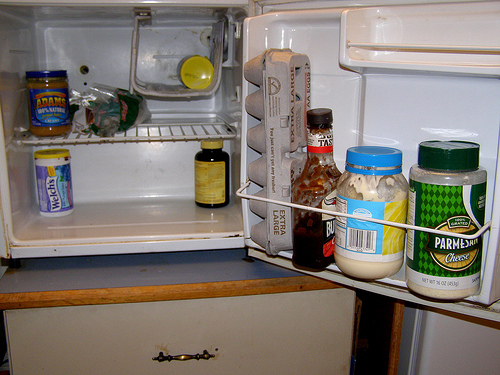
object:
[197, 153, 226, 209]
vitamins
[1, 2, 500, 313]
fridge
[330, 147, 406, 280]
mayonnaise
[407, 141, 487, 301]
parmesan cheese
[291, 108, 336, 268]
barbeque sauce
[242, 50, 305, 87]
eggs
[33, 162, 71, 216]
welch's drink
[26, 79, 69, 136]
sauce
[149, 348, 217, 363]
handle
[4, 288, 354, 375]
drawer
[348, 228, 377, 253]
barcode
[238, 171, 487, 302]
door shelf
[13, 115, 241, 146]
top shelf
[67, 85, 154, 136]
bag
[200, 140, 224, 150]
yellow lid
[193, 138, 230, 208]
bottle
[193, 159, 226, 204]
label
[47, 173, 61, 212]
letters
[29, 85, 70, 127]
label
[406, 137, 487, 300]
condiments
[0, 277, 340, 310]
seal